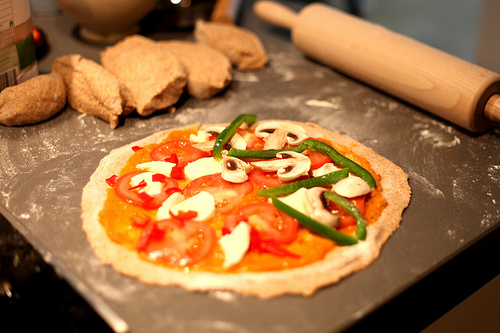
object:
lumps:
[4, 19, 274, 131]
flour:
[3, 131, 70, 232]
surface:
[4, 42, 499, 328]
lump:
[0, 63, 65, 140]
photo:
[1, 0, 491, 328]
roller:
[233, 1, 499, 150]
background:
[4, 0, 499, 56]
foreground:
[7, 111, 495, 329]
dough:
[79, 115, 417, 305]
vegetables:
[208, 113, 383, 270]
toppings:
[99, 107, 393, 276]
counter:
[12, 12, 490, 326]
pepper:
[212, 115, 376, 253]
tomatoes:
[107, 119, 387, 281]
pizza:
[80, 111, 414, 296]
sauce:
[98, 119, 380, 268]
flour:
[14, 117, 107, 152]